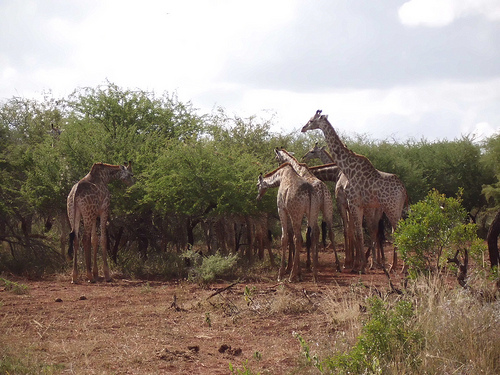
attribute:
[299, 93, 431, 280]
giraffe — brown, beige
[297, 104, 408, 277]
giraffe — standing, grouped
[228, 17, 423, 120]
clouds — white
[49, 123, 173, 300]
giraffe — feeding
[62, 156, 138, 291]
giraffe — standing alone, eating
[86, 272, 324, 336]
ground — dry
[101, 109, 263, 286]
trees — green